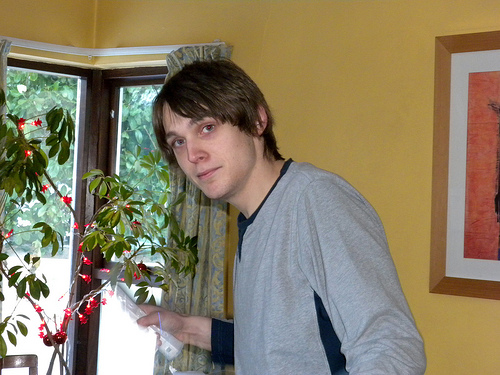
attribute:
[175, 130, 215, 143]
eyes — man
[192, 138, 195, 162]
nose — of the man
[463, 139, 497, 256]
picture — hanging, on the wall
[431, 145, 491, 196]
artwork — on the wall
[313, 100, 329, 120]
paint — yellow, on the walls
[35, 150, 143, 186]
windows — on the wall, large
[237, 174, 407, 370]
shirt — grey, black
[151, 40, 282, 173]
man's hair — straight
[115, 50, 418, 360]
man — gray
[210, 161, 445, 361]
shirt — black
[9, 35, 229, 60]
curtain rod — white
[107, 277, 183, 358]
object — white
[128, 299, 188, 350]
hand — man's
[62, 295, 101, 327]
berries — red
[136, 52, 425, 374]
man — young, blue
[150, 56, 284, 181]
hair — brown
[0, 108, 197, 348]
leaves — green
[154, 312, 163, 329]
stripe — thin, white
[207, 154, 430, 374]
shirt — gray, blue, white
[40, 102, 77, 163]
leaves — green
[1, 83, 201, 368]
plant — thin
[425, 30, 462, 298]
frame — wooden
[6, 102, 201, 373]
plant — green, small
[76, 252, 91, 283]
flowers — red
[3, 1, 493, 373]
walls — golden yellow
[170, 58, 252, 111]
hair — brown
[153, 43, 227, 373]
curtain — paisley